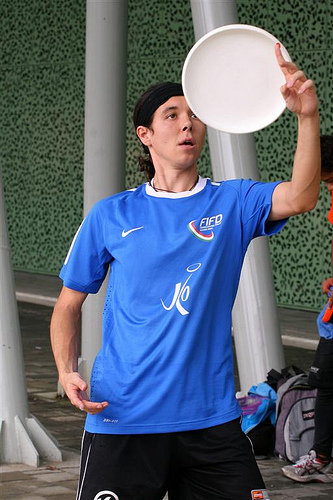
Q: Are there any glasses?
A: No, there are no glasses.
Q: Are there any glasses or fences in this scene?
A: No, there are no glasses or fences.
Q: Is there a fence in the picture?
A: No, there are no fences.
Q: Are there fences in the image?
A: No, there are no fences.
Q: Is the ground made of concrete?
A: Yes, the ground is made of concrete.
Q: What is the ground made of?
A: The ground is made of concrete.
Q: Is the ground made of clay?
A: No, the ground is made of cement.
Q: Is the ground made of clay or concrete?
A: The ground is made of concrete.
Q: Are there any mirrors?
A: No, there are no mirrors.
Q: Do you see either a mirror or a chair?
A: No, there are no mirrors or chairs.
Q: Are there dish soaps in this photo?
A: No, there are no dish soaps.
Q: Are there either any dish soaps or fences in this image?
A: No, there are no dish soaps or fences.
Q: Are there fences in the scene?
A: No, there are no fences.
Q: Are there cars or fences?
A: No, there are no fences or cars.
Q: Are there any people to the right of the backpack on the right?
A: Yes, there is a person to the right of the backpack.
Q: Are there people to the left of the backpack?
A: No, the person is to the right of the backpack.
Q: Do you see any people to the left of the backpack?
A: No, the person is to the right of the backpack.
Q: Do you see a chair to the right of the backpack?
A: No, there is a person to the right of the backpack.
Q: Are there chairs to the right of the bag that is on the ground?
A: No, there is a person to the right of the backpack.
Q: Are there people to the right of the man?
A: Yes, there is a person to the right of the man.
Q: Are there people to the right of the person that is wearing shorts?
A: Yes, there is a person to the right of the man.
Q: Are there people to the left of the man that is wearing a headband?
A: No, the person is to the right of the man.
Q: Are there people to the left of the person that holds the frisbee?
A: No, the person is to the right of the man.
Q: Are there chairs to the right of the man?
A: No, there is a person to the right of the man.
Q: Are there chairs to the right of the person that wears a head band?
A: No, there is a person to the right of the man.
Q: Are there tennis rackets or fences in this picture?
A: No, there are no fences or tennis rackets.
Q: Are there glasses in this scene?
A: No, there are no glasses.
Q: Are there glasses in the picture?
A: No, there are no glasses.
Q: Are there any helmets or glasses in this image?
A: No, there are no glasses or helmets.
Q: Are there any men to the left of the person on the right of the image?
A: Yes, there is a man to the left of the person.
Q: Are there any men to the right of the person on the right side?
A: No, the man is to the left of the person.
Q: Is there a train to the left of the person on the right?
A: No, there is a man to the left of the person.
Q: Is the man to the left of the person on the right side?
A: Yes, the man is to the left of the person.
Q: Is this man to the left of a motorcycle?
A: No, the man is to the left of the person.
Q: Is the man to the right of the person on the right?
A: No, the man is to the left of the person.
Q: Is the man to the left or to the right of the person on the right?
A: The man is to the left of the person.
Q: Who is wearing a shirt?
A: The man is wearing a shirt.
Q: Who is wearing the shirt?
A: The man is wearing a shirt.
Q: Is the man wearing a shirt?
A: Yes, the man is wearing a shirt.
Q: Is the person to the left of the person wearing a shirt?
A: Yes, the man is wearing a shirt.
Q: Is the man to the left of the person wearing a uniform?
A: No, the man is wearing a shirt.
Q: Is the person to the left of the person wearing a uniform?
A: No, the man is wearing a shirt.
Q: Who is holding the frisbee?
A: The man is holding the frisbee.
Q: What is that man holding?
A: The man is holding the frisbee.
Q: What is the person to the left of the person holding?
A: The man is holding the frisbee.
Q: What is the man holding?
A: The man is holding the frisbee.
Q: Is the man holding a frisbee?
A: Yes, the man is holding a frisbee.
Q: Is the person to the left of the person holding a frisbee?
A: Yes, the man is holding a frisbee.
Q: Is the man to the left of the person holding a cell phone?
A: No, the man is holding a frisbee.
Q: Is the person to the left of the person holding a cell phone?
A: No, the man is holding a frisbee.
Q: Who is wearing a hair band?
A: The man is wearing a hair band.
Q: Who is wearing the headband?
A: The man is wearing a hair band.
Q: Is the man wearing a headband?
A: Yes, the man is wearing a headband.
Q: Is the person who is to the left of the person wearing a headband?
A: Yes, the man is wearing a headband.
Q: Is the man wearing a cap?
A: No, the man is wearing a headband.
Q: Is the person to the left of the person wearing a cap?
A: No, the man is wearing a headband.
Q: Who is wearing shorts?
A: The man is wearing shorts.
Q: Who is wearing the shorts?
A: The man is wearing shorts.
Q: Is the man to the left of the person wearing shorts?
A: Yes, the man is wearing shorts.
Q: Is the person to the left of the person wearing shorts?
A: Yes, the man is wearing shorts.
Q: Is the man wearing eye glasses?
A: No, the man is wearing shorts.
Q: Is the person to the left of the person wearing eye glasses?
A: No, the man is wearing shorts.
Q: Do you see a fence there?
A: No, there are no fences.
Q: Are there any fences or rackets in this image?
A: No, there are no fences or rackets.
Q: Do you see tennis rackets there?
A: No, there are no tennis rackets.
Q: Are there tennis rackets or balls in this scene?
A: No, there are no tennis rackets or balls.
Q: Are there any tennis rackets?
A: No, there are no tennis rackets.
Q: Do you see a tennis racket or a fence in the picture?
A: No, there are no rackets or fences.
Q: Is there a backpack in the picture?
A: Yes, there is a backpack.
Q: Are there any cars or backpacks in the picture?
A: Yes, there is a backpack.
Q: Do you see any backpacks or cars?
A: Yes, there is a backpack.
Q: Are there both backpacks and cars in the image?
A: No, there is a backpack but no cars.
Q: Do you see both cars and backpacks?
A: No, there is a backpack but no cars.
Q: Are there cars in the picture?
A: No, there are no cars.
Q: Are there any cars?
A: No, there are no cars.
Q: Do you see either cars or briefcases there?
A: No, there are no cars or briefcases.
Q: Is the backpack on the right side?
A: Yes, the backpack is on the right of the image.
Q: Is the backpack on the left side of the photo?
A: No, the backpack is on the right of the image.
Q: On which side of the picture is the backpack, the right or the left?
A: The backpack is on the right of the image.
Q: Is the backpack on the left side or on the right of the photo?
A: The backpack is on the right of the image.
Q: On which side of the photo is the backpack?
A: The backpack is on the right of the image.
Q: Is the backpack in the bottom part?
A: Yes, the backpack is in the bottom of the image.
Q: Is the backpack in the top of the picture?
A: No, the backpack is in the bottom of the image.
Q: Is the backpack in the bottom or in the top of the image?
A: The backpack is in the bottom of the image.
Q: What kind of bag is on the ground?
A: The bag is a backpack.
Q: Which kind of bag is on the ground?
A: The bag is a backpack.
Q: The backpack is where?
A: The backpack is on the ground.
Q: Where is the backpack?
A: The backpack is on the ground.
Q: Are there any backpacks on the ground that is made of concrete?
A: Yes, there is a backpack on the ground.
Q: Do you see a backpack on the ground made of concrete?
A: Yes, there is a backpack on the ground.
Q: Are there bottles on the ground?
A: No, there is a backpack on the ground.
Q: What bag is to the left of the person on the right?
A: The bag is a backpack.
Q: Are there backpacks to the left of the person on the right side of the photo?
A: Yes, there is a backpack to the left of the person.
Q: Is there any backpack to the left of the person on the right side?
A: Yes, there is a backpack to the left of the person.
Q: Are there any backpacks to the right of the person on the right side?
A: No, the backpack is to the left of the person.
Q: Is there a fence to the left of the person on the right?
A: No, there is a backpack to the left of the person.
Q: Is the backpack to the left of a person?
A: Yes, the backpack is to the left of a person.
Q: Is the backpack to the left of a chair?
A: No, the backpack is to the left of a person.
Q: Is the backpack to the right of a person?
A: No, the backpack is to the left of a person.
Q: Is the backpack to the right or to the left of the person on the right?
A: The backpack is to the left of the person.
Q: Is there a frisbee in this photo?
A: Yes, there is a frisbee.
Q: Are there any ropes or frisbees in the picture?
A: Yes, there is a frisbee.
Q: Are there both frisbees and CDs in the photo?
A: No, there is a frisbee but no cds.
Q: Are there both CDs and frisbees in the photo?
A: No, there is a frisbee but no cds.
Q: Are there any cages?
A: No, there are no cages.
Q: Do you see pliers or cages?
A: No, there are no cages or pliers.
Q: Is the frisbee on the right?
A: Yes, the frisbee is on the right of the image.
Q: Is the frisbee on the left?
A: No, the frisbee is on the right of the image.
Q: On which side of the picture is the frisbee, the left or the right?
A: The frisbee is on the right of the image.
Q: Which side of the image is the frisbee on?
A: The frisbee is on the right of the image.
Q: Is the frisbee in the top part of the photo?
A: Yes, the frisbee is in the top of the image.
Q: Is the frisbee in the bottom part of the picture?
A: No, the frisbee is in the top of the image.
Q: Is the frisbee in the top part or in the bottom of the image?
A: The frisbee is in the top of the image.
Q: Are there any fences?
A: No, there are no fences.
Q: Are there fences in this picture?
A: No, there are no fences.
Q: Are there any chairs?
A: No, there are no chairs.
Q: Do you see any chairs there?
A: No, there are no chairs.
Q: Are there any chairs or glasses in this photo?
A: No, there are no chairs or glasses.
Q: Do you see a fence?
A: No, there are no fences.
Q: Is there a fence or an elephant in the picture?
A: No, there are no fences or elephants.